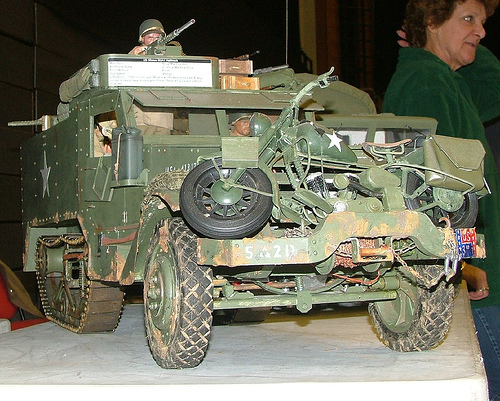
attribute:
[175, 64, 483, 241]
motorcycle — green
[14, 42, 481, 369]
tank — metal, toy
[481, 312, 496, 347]
jeans — blue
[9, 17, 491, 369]
tank figurine — tall green 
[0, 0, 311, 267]
wall — brown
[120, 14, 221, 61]
gunner — toy soldier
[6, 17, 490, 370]
army tanker — toy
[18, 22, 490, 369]
jeep — military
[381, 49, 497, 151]
sweater — green 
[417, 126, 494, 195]
saddle bag — green, arny, motorcycle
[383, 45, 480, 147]
shirt — green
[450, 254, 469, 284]
bracelet — gold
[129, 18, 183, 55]
soldier figurine — one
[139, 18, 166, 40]
helmet — green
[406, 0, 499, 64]
hair — curly, brown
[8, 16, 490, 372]
army tank — toy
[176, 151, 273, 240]
wheel — one, round, black, motorcycle wheel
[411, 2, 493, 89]
caucasian woman — Caucasian 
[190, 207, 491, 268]
bumper — green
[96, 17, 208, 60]
soldier — statue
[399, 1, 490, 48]
hair — brown, short 